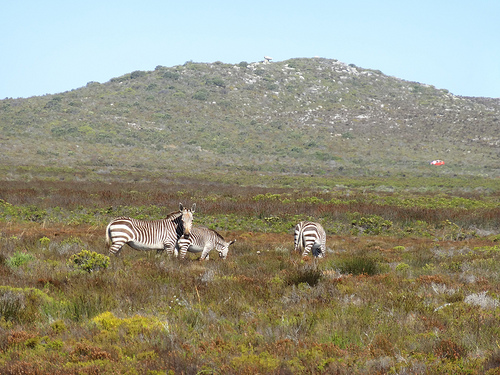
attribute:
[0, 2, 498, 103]
sky — blue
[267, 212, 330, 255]
zebras — eating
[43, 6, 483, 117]
sky — cloudless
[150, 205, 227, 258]
head — white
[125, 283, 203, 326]
flowers — white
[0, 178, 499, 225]
plants — brown